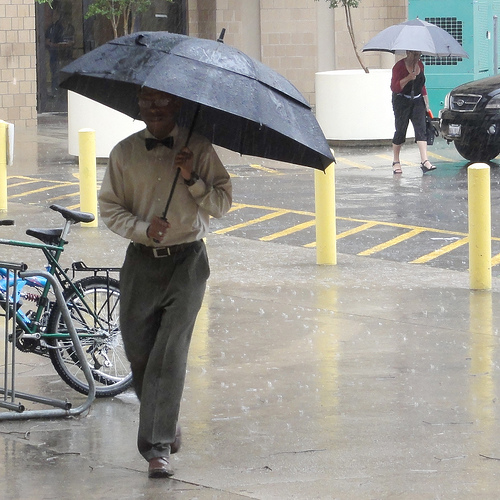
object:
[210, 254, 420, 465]
rain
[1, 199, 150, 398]
bikes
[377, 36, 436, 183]
woman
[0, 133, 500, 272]
street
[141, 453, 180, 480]
shoes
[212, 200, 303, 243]
lines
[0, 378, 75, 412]
rack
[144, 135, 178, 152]
bow tie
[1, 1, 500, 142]
building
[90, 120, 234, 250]
shirt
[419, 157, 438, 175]
sandals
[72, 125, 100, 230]
pole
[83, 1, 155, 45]
tree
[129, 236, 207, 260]
belt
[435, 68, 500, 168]
suv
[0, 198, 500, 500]
sidewalk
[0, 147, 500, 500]
floor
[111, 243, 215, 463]
trousers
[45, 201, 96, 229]
seat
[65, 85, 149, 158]
container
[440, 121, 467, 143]
bumper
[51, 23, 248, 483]
man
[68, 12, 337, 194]
umbrella